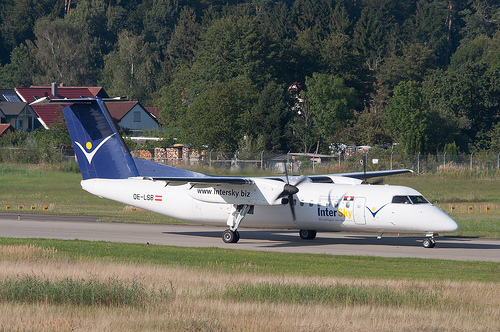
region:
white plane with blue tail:
[34, 95, 456, 247]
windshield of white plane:
[392, 193, 432, 205]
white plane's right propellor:
[277, 162, 308, 220]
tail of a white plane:
[30, 96, 140, 177]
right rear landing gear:
[222, 228, 242, 243]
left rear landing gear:
[299, 226, 316, 238]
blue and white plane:
[62, 99, 467, 266]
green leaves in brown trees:
[373, 12, 408, 53]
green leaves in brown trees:
[417, 76, 461, 120]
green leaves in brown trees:
[323, 51, 365, 95]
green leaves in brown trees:
[232, 26, 266, 64]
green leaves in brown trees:
[170, 78, 221, 112]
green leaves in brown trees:
[150, 35, 198, 72]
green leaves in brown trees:
[242, 22, 293, 73]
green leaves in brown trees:
[332, 21, 416, 81]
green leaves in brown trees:
[419, 31, 494, 83]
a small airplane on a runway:
[27, 93, 458, 247]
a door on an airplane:
[353, 195, 367, 226]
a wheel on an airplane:
[221, 229, 241, 243]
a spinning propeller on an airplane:
[270, 162, 309, 221]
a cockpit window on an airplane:
[407, 192, 425, 202]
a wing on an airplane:
[144, 173, 252, 187]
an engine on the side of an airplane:
[186, 178, 286, 203]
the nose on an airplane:
[429, 204, 459, 238]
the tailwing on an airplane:
[35, 91, 148, 173]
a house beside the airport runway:
[27, 97, 161, 138]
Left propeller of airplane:
[265, 153, 316, 228]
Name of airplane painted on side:
[306, 200, 360, 228]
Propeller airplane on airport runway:
[10, 79, 467, 254]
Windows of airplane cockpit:
[383, 187, 433, 213]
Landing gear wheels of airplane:
[212, 220, 252, 247]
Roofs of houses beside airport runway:
[13, 80, 167, 150]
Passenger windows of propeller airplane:
[291, 196, 321, 210]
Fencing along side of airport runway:
[176, 143, 491, 175]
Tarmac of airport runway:
[17, 211, 497, 268]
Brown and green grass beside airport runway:
[15, 251, 323, 321]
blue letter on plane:
[196, 186, 203, 193]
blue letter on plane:
[200, 187, 207, 195]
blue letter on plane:
[205, 188, 213, 194]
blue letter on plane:
[214, 188, 219, 193]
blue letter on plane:
[238, 190, 245, 197]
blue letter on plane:
[245, 190, 252, 200]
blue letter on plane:
[316, 205, 321, 216]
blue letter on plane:
[319, 208, 326, 216]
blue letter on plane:
[323, 205, 329, 217]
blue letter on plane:
[327, 207, 333, 217]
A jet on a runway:
[30, 82, 458, 247]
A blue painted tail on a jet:
[34, 94, 139, 177]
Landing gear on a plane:
[218, 225, 238, 240]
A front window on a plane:
[389, 194, 427, 204]